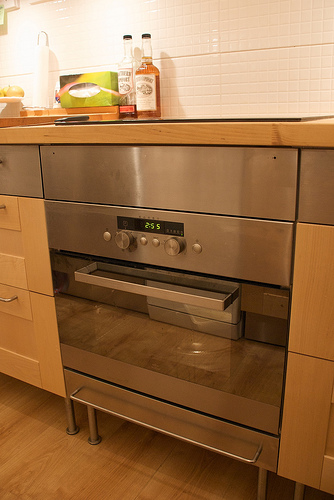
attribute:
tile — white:
[219, 54, 276, 115]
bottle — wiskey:
[119, 29, 134, 120]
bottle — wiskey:
[138, 30, 158, 118]